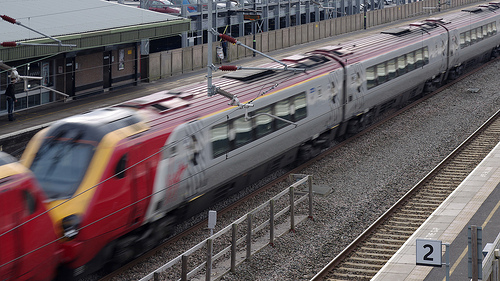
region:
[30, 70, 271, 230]
this is the train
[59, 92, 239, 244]
the train is moving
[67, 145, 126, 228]
the train is red in color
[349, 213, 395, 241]
this is the rail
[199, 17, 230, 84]
this is a pole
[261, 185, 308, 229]
this is a fence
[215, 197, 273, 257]
the fence is metallic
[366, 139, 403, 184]
these are small stones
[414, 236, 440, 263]
it is written number2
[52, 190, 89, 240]
these are electric wires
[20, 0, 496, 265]
red and silver train at the station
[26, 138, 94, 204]
window on a red and silver train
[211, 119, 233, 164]
window on a red and silver train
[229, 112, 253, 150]
window on a red and silver train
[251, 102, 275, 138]
window on a red and silver train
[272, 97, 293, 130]
window on a red and silver train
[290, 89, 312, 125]
window on a red and silver train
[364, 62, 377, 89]
window on a red and silver train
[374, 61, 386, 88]
window on a red and silver train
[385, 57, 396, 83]
window on a red and silver train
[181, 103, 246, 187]
this is a train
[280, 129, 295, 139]
the train is white in color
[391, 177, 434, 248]
this is a railway line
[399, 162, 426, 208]
this is a metal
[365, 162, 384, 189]
these are small rocks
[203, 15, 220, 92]
this is a pole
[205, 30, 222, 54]
the pole is white in color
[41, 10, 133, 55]
this is a building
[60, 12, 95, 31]
this is the roof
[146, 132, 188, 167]
this is a electrical wire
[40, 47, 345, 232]
Section of a train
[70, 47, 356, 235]
Section of a train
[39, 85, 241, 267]
Section of a train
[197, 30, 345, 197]
Section of a train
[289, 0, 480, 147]
Section of a train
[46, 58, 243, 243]
Section of a train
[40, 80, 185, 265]
Section of a train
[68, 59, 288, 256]
Section of a train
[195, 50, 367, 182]
Section of a train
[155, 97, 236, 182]
this is a train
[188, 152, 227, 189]
the train is white in color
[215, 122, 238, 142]
this is a window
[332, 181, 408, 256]
this is a railway line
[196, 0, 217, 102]
this is a pole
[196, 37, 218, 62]
the pole is white in color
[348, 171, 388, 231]
these are small rocks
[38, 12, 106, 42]
this is a roof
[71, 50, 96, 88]
this is the wall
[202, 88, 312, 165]
Windows of a train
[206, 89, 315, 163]
Windows of a train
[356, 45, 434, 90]
Windows of a train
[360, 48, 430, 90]
Windows of a train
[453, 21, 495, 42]
Windows of a train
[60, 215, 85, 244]
Headlight of a train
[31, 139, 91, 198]
Window of a train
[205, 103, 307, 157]
Windows of a train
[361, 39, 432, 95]
Windows of a train